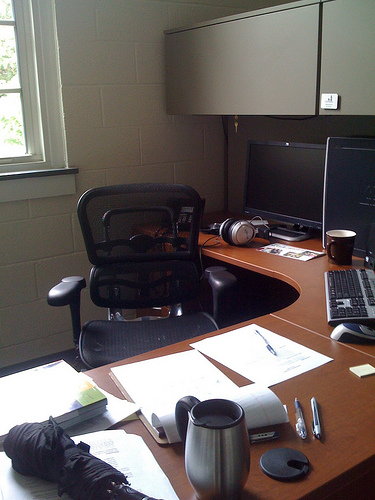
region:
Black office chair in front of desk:
[46, 178, 237, 363]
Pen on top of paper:
[254, 331, 277, 355]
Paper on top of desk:
[189, 319, 332, 385]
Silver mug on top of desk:
[173, 394, 253, 499]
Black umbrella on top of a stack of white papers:
[1, 414, 163, 498]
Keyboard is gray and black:
[324, 266, 373, 326]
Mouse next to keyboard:
[325, 324, 373, 348]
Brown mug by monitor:
[326, 226, 359, 266]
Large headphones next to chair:
[214, 213, 277, 247]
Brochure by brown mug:
[256, 241, 326, 261]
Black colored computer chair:
[45, 181, 232, 362]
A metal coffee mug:
[172, 392, 249, 497]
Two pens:
[291, 393, 318, 438]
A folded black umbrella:
[1, 416, 155, 492]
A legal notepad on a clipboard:
[107, 345, 242, 435]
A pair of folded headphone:
[218, 214, 265, 244]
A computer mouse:
[330, 320, 373, 343]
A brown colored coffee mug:
[323, 227, 353, 264]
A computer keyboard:
[324, 265, 372, 319]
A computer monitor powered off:
[243, 138, 324, 230]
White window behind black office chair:
[0, 0, 68, 163]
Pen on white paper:
[254, 324, 278, 357]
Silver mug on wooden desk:
[172, 395, 252, 498]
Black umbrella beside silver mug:
[3, 413, 160, 498]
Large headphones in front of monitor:
[220, 212, 253, 243]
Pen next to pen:
[291, 392, 310, 439]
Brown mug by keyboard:
[323, 224, 353, 260]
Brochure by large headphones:
[256, 241, 325, 260]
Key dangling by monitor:
[231, 121, 238, 133]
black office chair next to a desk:
[48, 174, 220, 335]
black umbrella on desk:
[0, 401, 126, 495]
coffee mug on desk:
[184, 385, 260, 497]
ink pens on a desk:
[251, 379, 321, 461]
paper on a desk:
[208, 308, 328, 385]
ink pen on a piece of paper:
[252, 315, 276, 361]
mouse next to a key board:
[333, 313, 371, 337]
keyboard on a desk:
[325, 256, 370, 319]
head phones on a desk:
[213, 205, 267, 243]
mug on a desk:
[229, 218, 355, 261]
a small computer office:
[36, 101, 364, 318]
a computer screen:
[219, 136, 373, 257]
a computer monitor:
[309, 127, 373, 269]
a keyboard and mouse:
[299, 220, 373, 348]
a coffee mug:
[148, 365, 304, 495]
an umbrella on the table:
[5, 411, 171, 498]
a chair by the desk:
[42, 179, 235, 363]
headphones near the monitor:
[202, 192, 294, 266]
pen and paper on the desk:
[94, 315, 331, 449]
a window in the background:
[4, 2, 102, 180]